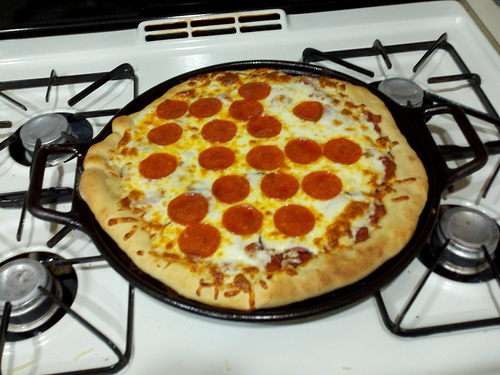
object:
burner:
[350, 30, 484, 157]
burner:
[369, 152, 499, 336]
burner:
[0, 201, 137, 373]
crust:
[80, 67, 429, 312]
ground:
[408, 167, 458, 236]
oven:
[1, 3, 497, 372]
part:
[137, 319, 393, 372]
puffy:
[81, 143, 106, 211]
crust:
[78, 120, 127, 246]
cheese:
[150, 180, 186, 196]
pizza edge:
[76, 143, 115, 209]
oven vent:
[129, 7, 291, 47]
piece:
[176, 227, 223, 258]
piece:
[320, 140, 366, 161]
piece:
[303, 167, 343, 201]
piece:
[234, 79, 278, 100]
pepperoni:
[147, 123, 182, 143]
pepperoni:
[231, 96, 263, 121]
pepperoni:
[325, 136, 363, 163]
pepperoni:
[247, 145, 286, 170]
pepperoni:
[169, 190, 205, 224]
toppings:
[225, 100, 267, 121]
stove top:
[0, 0, 496, 372]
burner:
[1, 61, 138, 194]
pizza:
[77, 65, 426, 310]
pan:
[27, 57, 484, 324]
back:
[2, 0, 140, 29]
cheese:
[279, 119, 369, 138]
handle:
[415, 86, 482, 187]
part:
[241, 272, 282, 302]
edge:
[82, 166, 89, 175]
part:
[397, 284, 422, 314]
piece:
[135, 150, 180, 182]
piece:
[161, 188, 211, 224]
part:
[26, 274, 71, 315]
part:
[412, 48, 452, 80]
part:
[17, 128, 42, 158]